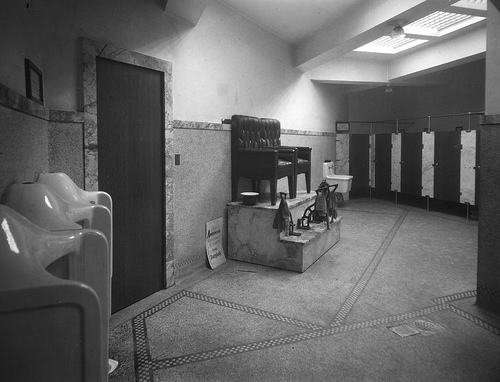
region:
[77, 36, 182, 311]
Door in the bathroom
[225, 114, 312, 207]
Cushioned seats atop of stair steps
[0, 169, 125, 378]
Urinals for use in the bathroom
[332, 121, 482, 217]
Bathroom stalls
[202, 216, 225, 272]
Flyer with directions for use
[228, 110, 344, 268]
Seats for polishing shoes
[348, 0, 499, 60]
Bright luminescence lights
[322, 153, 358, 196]
Short sink for washing hands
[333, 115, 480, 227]
Row of closed bathroom stalls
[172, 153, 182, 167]
Bathroom light switch next to door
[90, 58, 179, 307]
door that is closed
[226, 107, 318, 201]
two chairs sitting on a pedestal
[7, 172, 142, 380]
row of urinals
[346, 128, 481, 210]
row of closed stalls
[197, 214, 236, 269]
sign leaning up against the wall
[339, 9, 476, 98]
two lights on the ceiling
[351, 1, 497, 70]
lights that are on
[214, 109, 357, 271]
shoe shining station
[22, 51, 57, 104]
frame on the ledge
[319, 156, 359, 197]
white sink on the wall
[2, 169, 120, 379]
Wall urinals in men's washroom.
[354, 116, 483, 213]
Four bathroom stalls.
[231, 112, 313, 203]
Shoeshine chair atop a stand.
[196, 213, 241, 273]
Sign promoting a concert.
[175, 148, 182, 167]
Light switch on the right side of the door.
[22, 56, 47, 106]
Certificate of cleanliness for the washroom.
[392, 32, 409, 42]
Exit exhaust fan to remove unpleasant ordors.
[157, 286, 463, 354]
Geometric floor tile design.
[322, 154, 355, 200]
Mensroom white wash tub basin.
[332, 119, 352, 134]
Maximum capacity information sign.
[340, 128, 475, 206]
row of stalls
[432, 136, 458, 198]
black stall door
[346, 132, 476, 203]
stall doors are closed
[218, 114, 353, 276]
shoe shining station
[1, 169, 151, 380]
three urinals on the wall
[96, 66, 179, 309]
dark brown wooden door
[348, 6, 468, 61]
the lights are on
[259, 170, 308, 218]
shoe shine seats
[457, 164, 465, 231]
bathroom stalls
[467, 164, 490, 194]
doors on the stalls are white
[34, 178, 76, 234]
urinals on the wall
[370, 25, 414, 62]
lights in the ceiling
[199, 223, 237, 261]
sign up against the wall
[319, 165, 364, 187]
sink next to stalls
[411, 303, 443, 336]
drain in the floor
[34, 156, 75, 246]
three urinals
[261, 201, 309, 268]
steps on the shoe shining stand